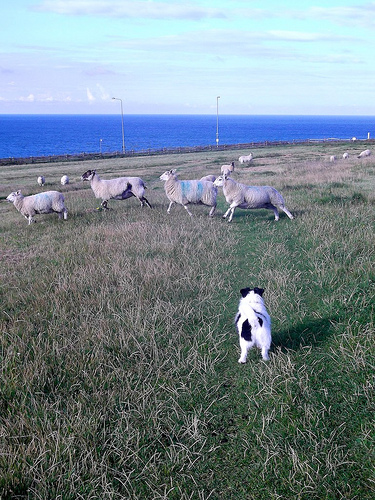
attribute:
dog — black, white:
[238, 283, 283, 375]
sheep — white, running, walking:
[14, 166, 284, 230]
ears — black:
[240, 283, 274, 303]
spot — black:
[237, 318, 262, 343]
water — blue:
[2, 107, 88, 159]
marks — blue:
[174, 179, 210, 203]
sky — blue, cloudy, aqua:
[64, 10, 194, 85]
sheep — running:
[77, 161, 158, 212]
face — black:
[76, 166, 106, 191]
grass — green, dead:
[31, 235, 213, 418]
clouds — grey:
[155, 17, 277, 64]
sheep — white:
[212, 170, 294, 218]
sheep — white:
[7, 186, 68, 223]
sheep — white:
[156, 168, 217, 217]